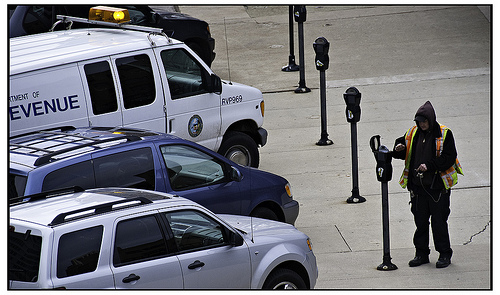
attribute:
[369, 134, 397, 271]
meter — here, black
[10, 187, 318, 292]
suv — silver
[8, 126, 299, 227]
van — blue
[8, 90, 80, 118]
text — blue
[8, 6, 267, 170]
van — white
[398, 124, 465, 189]
vest — orange, green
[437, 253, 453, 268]
shoes — black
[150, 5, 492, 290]
sidewalk — tan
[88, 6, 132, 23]
light — yellow, orange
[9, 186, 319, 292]
vehicle — parked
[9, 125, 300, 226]
vehicle — blue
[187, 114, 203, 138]
emblem — circle